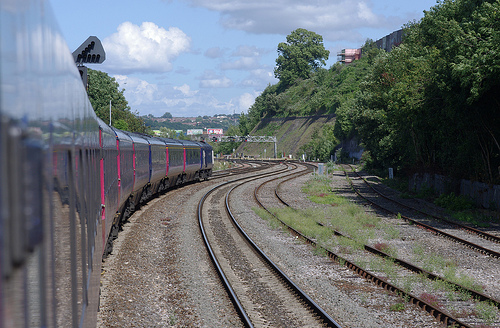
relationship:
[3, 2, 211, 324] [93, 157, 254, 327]
train on track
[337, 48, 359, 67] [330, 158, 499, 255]
building over looking track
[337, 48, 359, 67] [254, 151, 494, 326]
building over looking track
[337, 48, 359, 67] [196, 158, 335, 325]
building over looking track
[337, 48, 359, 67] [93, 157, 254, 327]
building over looking track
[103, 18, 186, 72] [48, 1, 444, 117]
cloud in sky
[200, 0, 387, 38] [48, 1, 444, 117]
cloud in sky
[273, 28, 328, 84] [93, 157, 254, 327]
tree beside track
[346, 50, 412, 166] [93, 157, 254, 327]
tree beside track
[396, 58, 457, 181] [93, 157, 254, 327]
tree beside track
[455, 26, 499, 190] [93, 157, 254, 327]
tree beside track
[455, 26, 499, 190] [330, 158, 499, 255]
tree beside track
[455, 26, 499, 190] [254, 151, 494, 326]
tree beside track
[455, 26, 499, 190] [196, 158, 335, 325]
tree beside track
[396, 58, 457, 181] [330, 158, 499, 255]
tree beside track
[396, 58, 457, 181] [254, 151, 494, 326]
tree beside track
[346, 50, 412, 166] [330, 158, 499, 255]
tree beside track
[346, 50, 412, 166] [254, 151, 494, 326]
tree beside track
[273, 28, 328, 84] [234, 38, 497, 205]
tree on hillside